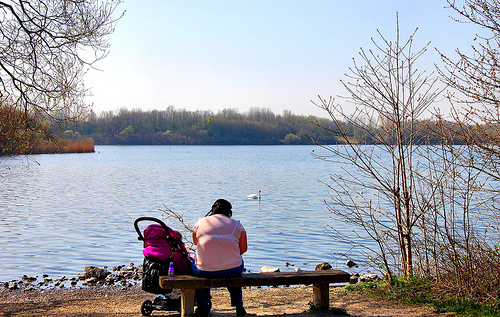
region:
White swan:
[226, 177, 286, 215]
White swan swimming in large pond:
[226, 172, 286, 220]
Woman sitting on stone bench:
[118, 185, 308, 315]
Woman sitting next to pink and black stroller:
[132, 190, 288, 315]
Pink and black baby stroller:
[132, 212, 197, 316]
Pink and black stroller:
[130, 206, 211, 316]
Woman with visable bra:
[187, 191, 266, 316]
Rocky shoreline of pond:
[0, 254, 142, 312]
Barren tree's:
[308, 5, 498, 287]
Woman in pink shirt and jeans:
[130, 187, 355, 315]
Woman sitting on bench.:
[190, 195, 256, 312]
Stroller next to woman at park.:
[124, 213, 210, 309]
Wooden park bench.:
[160, 259, 348, 315]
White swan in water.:
[233, 177, 269, 207]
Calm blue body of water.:
[105, 149, 341, 178]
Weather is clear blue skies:
[140, 13, 325, 103]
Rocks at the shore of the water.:
[10, 267, 150, 287]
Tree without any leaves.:
[312, 14, 461, 278]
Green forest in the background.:
[116, 106, 333, 145]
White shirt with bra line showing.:
[186, 213, 243, 273]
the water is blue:
[87, 151, 147, 200]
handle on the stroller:
[133, 213, 160, 225]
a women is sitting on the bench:
[190, 202, 247, 272]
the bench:
[251, 272, 296, 282]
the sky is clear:
[211, 37, 314, 78]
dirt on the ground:
[361, 302, 398, 316]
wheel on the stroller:
[136, 297, 154, 315]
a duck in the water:
[246, 184, 265, 201]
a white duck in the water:
[245, 186, 265, 201]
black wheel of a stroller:
[138, 298, 155, 315]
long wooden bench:
[157, 266, 351, 312]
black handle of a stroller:
[131, 215, 178, 246]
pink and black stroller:
[131, 209, 215, 313]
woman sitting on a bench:
[155, 195, 355, 312]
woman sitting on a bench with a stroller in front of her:
[130, 191, 354, 315]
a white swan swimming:
[242, 185, 264, 202]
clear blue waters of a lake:
[0, 133, 498, 288]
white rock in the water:
[258, 263, 282, 274]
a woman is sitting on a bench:
[188, 198, 248, 311]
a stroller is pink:
[132, 216, 207, 314]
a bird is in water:
[248, 187, 263, 202]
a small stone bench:
[158, 270, 345, 313]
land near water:
[0, 102, 92, 157]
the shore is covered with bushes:
[68, 110, 499, 155]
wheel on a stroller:
[140, 300, 154, 315]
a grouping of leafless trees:
[316, 11, 471, 291]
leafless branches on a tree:
[1, 1, 128, 141]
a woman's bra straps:
[195, 216, 242, 246]